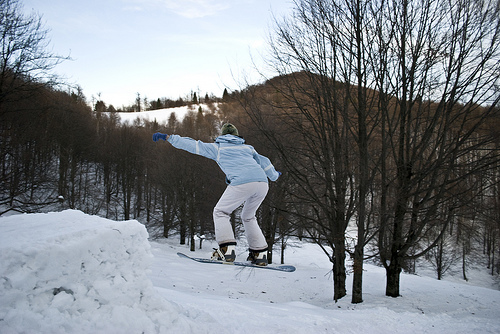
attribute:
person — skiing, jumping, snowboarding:
[149, 108, 283, 265]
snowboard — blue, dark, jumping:
[172, 251, 298, 274]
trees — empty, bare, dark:
[1, 1, 499, 304]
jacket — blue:
[165, 131, 277, 185]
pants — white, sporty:
[214, 180, 270, 252]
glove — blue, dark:
[149, 129, 168, 141]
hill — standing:
[79, 69, 322, 137]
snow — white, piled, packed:
[94, 101, 224, 124]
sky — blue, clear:
[2, 1, 492, 111]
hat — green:
[219, 121, 240, 137]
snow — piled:
[2, 208, 187, 334]